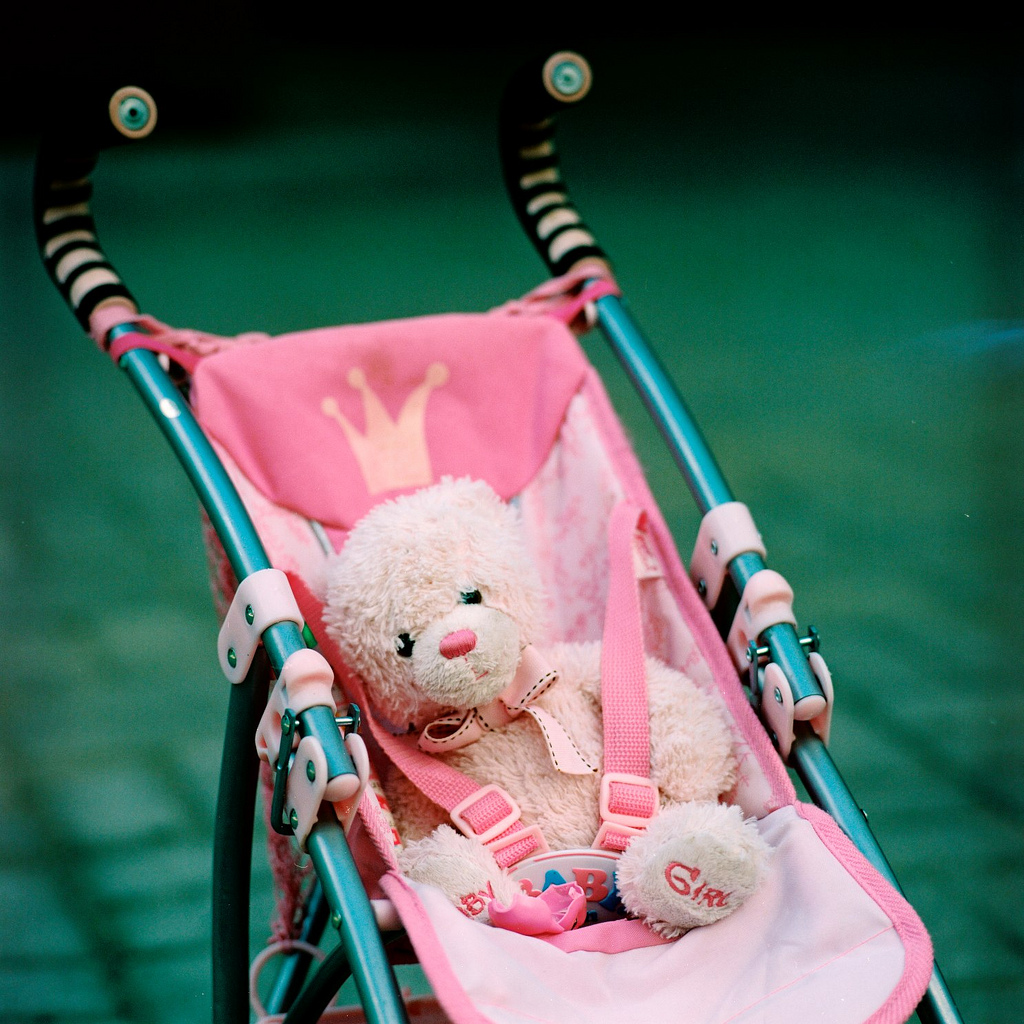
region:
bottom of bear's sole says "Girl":
[619, 801, 762, 928]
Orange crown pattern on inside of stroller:
[298, 356, 477, 500]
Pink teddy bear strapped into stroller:
[284, 477, 779, 927]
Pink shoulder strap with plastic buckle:
[301, 597, 561, 905]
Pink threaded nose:
[435, 628, 473, 661]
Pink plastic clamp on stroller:
[198, 571, 301, 671]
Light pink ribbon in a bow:
[408, 669, 623, 787]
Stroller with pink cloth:
[19, 41, 968, 1021]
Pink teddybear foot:
[411, 821, 528, 943]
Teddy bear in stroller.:
[176, 292, 807, 1021]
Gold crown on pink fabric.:
[289, 336, 464, 501]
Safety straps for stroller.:
[398, 737, 523, 903]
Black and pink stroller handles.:
[30, 89, 187, 375]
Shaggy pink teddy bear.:
[320, 475, 732, 934]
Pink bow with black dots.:
[403, 655, 585, 780]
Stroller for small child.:
[57, 59, 940, 1008]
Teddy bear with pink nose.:
[328, 489, 553, 723]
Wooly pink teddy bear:
[324, 475, 764, 937]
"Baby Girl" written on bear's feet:
[387, 801, 767, 934]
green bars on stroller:
[103, 319, 410, 1022]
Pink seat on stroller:
[117, 301, 936, 1013]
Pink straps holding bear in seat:
[289, 478, 651, 859]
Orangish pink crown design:
[317, 344, 450, 500]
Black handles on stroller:
[36, 42, 626, 331]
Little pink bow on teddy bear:
[413, 643, 594, 774]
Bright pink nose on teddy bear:
[437, 623, 476, 665]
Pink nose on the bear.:
[431, 619, 486, 662]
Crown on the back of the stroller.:
[322, 344, 479, 478]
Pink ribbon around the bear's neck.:
[414, 673, 589, 791]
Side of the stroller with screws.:
[188, 575, 338, 771]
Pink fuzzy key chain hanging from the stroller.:
[258, 813, 303, 953]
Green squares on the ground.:
[52, 745, 129, 843]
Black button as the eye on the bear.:
[450, 574, 507, 601]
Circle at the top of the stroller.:
[542, 48, 606, 97]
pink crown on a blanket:
[291, 332, 576, 482]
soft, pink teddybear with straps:
[343, 482, 743, 929]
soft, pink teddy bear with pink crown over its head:
[309, 361, 782, 924]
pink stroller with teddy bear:
[147, 307, 929, 960]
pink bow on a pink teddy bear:
[343, 475, 613, 779]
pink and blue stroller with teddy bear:
[138, 319, 635, 893]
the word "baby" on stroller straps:
[467, 778, 677, 931]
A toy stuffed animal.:
[337, 454, 761, 930]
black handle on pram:
[462, 66, 622, 218]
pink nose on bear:
[380, 610, 540, 697]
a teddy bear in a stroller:
[285, 402, 804, 1017]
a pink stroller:
[299, 307, 805, 1013]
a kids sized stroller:
[200, 216, 906, 1019]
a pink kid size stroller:
[182, 219, 783, 950]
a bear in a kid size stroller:
[286, 478, 836, 1010]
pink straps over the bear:
[412, 404, 808, 929]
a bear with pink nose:
[434, 436, 650, 778]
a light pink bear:
[312, 420, 791, 971]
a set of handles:
[18, 47, 686, 386]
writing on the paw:
[648, 844, 744, 925]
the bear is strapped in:
[298, 451, 735, 996]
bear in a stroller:
[64, 57, 940, 1022]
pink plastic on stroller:
[187, 555, 403, 850]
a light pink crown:
[316, 347, 466, 497]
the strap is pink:
[568, 486, 673, 842]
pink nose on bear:
[432, 628, 491, 674]